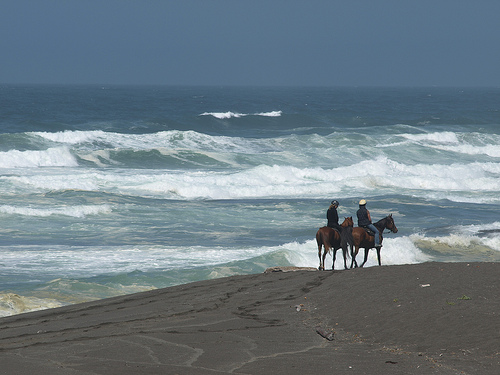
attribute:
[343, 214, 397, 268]
horse — walking, brown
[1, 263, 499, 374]
beach — dark, sandy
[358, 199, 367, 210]
helmet — white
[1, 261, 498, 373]
sand — upturned, black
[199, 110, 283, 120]
wave — white, breaking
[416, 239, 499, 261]
foam — brownish, dirty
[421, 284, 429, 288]
stick — small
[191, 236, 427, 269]
wave — big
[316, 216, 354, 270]
horse — brown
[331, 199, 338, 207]
helmet — black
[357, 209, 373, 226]
shirt — blue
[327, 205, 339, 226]
shirt — black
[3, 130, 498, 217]
wave — big, large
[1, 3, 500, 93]
sky — stormy